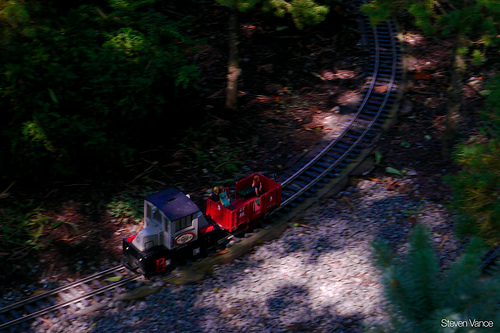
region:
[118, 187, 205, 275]
The engine of the toy train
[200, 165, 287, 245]
The red car of the train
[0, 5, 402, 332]
The tracks of the train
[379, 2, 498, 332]
The trees on the right of the photo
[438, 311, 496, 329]
The name of the photographer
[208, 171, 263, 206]
The people on the train car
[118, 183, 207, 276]
The grey portion of the train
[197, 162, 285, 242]
The red portion of the train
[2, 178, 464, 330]
The gravel to the train tracks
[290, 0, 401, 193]
The tracks behind the train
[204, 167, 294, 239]
train car is red and small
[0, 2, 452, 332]
Long curved train track with train on it.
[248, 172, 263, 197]
Littler person sitting in the back of a red car on a train.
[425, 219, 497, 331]
Barely visible piece of train track.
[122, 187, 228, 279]
Front of a train on a track.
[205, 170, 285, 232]
Red train car being pulled behind a train.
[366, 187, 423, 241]
Shadow on the ground beside a train track.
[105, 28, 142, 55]
Many green leaves on a tree.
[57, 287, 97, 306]
Light shining on a small piece of train track.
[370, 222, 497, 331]
Pine tree beside a small piece of train track.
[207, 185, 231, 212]
Two people sitting in a red car on a train.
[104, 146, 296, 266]
Toy train in a rail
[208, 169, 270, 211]
Figure toys are on red cart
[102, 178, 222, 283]
Driver cabin of toy train is purple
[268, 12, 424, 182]
Rail of toy train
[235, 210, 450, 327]
Gravel next to rail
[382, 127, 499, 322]
Green plants on right side of train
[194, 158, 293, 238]
Train has a red cart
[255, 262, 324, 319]
Shadow cast on gravel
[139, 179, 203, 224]
Roof of train is purple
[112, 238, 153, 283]
Bumper of train is green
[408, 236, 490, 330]
this is a flower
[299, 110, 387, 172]
this is a railway line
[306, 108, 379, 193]
the railway line is long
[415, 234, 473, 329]
the flower is green in color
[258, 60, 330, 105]
this is a soil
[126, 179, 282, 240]
this is a train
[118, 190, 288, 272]
the train is small in size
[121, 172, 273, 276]
the train is red,blue and silver in color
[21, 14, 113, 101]
this are leaves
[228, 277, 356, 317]
these are ballast